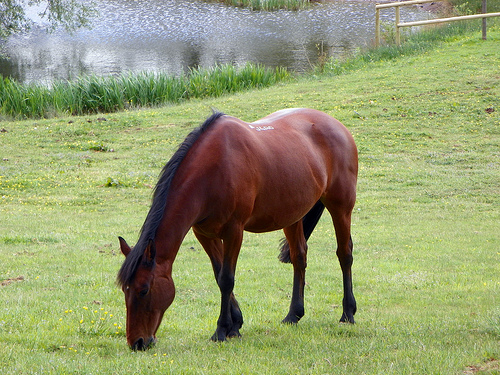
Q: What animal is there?
A: Horse.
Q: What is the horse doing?
A: Eating.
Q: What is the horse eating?
A: Grass.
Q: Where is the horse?
A: Grass field.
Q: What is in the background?
A: Water.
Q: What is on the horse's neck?
A: Hair.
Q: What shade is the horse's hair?
A: Black.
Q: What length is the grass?
A: Tall.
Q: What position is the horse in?
A: Standing.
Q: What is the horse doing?
A: It is grazing.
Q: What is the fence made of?
A: Wood.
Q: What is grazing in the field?
A: Brown horse with black mane.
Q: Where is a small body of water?
A: Behind the horse.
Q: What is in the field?
A: A horse.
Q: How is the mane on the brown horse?
A: Black.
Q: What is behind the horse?
A: Water.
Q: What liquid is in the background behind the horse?
A: Water.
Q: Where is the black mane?
A: On the horse's head and down the back of its neck.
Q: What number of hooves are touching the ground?
A: 4.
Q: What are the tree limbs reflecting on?
A: Water.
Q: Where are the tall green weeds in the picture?
A: On the bank of the pond.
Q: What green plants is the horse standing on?
A: Grass.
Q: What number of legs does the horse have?
A: 4.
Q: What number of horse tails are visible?
A: 1.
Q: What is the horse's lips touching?
A: Grass.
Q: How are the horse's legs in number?
A: Four.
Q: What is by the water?
A: Grass.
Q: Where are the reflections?
A: In the water.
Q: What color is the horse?
A: Brown.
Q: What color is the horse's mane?
A: Black.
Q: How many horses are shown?
A: One.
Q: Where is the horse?
A: In grass.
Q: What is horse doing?
A: Grazing.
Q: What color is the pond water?
A: Gray.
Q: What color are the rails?
A: Yellow.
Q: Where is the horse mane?
A: On back.